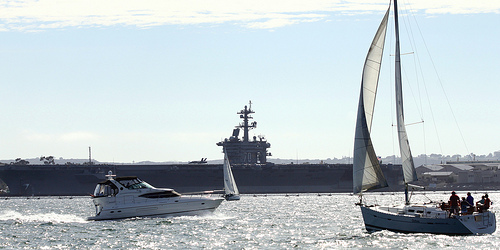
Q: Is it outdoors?
A: Yes, it is outdoors.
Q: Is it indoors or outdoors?
A: It is outdoors.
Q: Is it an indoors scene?
A: No, it is outdoors.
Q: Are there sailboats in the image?
A: Yes, there is a sailboat.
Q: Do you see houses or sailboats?
A: Yes, there is a sailboat.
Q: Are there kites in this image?
A: No, there are no kites.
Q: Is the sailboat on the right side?
A: Yes, the sailboat is on the right of the image.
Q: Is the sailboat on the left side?
A: No, the sailboat is on the right of the image.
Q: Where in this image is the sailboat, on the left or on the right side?
A: The sailboat is on the right of the image.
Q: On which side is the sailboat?
A: The sailboat is on the right of the image.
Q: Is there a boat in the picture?
A: Yes, there is a boat.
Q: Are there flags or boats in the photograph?
A: Yes, there is a boat.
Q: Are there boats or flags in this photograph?
A: Yes, there is a boat.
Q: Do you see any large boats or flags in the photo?
A: Yes, there is a large boat.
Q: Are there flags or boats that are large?
A: Yes, the boat is large.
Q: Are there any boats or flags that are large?
A: Yes, the boat is large.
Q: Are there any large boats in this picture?
A: Yes, there is a large boat.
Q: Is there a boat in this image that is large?
A: Yes, there is a boat that is large.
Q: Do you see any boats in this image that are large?
A: Yes, there is a boat that is large.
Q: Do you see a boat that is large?
A: Yes, there is a boat that is large.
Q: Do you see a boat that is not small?
A: Yes, there is a large boat.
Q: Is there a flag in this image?
A: No, there are no flags.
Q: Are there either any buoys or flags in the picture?
A: No, there are no flags or buoys.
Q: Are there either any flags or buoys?
A: No, there are no flags or buoys.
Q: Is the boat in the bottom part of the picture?
A: Yes, the boat is in the bottom of the image.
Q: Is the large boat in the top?
A: No, the boat is in the bottom of the image.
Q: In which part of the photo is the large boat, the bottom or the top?
A: The boat is in the bottom of the image.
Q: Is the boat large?
A: Yes, the boat is large.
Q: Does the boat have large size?
A: Yes, the boat is large.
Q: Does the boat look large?
A: Yes, the boat is large.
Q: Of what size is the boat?
A: The boat is large.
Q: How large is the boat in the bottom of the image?
A: The boat is large.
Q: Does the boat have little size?
A: No, the boat is large.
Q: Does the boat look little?
A: No, the boat is large.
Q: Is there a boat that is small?
A: No, there is a boat but it is large.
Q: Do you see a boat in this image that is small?
A: No, there is a boat but it is large.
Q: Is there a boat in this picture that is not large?
A: No, there is a boat but it is large.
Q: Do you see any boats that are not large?
A: No, there is a boat but it is large.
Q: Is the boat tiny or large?
A: The boat is large.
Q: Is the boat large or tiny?
A: The boat is large.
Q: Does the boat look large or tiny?
A: The boat is large.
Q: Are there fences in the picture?
A: No, there are no fences.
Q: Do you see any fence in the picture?
A: No, there are no fences.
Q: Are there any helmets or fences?
A: No, there are no fences or helmets.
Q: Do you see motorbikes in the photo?
A: No, there are no motorbikes.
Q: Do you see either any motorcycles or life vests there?
A: No, there are no motorcycles or life vests.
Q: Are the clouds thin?
A: Yes, the clouds are thin.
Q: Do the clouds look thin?
A: Yes, the clouds are thin.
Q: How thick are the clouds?
A: The clouds are thin.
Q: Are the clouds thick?
A: No, the clouds are thin.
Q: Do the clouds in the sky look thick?
A: No, the clouds are thin.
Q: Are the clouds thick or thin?
A: The clouds are thin.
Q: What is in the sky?
A: The clouds are in the sky.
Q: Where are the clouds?
A: The clouds are in the sky.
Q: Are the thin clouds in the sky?
A: Yes, the clouds are in the sky.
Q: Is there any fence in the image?
A: No, there are no fences.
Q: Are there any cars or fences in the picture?
A: No, there are no fences or cars.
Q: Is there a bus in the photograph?
A: No, there are no buses.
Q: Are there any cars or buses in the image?
A: No, there are no buses or cars.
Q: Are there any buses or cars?
A: No, there are no buses or cars.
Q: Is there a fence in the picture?
A: No, there are no fences.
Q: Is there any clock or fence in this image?
A: No, there are no fences or clocks.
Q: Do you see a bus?
A: No, there are no buses.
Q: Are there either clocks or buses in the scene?
A: No, there are no buses or clocks.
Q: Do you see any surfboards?
A: No, there are no surfboards.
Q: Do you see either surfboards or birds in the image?
A: No, there are no surfboards or birds.